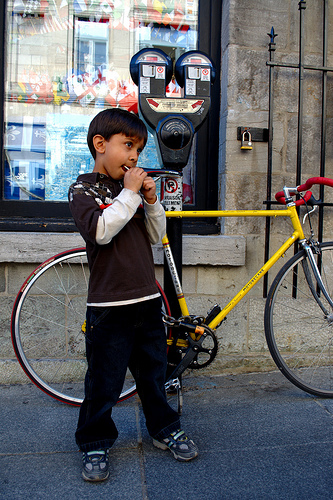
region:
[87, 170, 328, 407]
the bike is yellow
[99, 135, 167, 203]
little boy has sucker in mouth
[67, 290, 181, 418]
boy's pants are black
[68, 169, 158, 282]
boy's shirt is brown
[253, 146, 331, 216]
bike has red handles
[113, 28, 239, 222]
parking meter behind boy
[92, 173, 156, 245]
shirt has white sleeves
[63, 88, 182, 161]
boy's hair is brown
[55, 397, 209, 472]
shoes have velcro straps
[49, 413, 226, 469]
the shoes are gray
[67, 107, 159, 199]
young boy with popsicle in his mouth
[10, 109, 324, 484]
young boy standing in front of a bike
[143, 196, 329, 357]
a yellow frame on a bike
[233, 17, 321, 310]
a patalock on a gate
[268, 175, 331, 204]
red handle bars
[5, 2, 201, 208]
reflection of a building in the window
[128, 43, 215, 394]
a black parking meter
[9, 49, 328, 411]
a bike leaning against parking meter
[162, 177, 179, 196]
a small no parking sticker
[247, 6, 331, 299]
a black iron gate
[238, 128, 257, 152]
Silver and yellow padlock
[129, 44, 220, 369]
Dual side parking meter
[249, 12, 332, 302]
A black wrought iron fence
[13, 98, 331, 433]
A child in front of a bike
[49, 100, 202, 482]
Little boy enjoying a sucker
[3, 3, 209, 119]
Shop window displaying flags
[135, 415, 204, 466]
Gray and blue tennis shoe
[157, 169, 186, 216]
No parking sign on pole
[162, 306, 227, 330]
bike security chain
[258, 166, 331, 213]
red bike handle bars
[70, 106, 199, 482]
A young boy biting a white object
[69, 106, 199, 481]
A young boy wearing jeans and sneakers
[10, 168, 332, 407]
A red, black and yellow racing bike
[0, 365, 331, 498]
Black cemented passage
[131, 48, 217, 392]
A parking meter in a street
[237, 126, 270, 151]
Dark and yellow colored padlock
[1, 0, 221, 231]
A black frame window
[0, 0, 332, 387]
A building block next to the parking lot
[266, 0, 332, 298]
A metallic grille mounted to the building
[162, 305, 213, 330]
Chains fastening the racing bike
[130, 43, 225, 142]
a parking meter at the side of a road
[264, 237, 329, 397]
the wheel of a bicycle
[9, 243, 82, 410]
the wheel of a bicycle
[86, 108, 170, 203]
a little boy eating something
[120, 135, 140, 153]
the eye of a child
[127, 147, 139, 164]
the nose of a child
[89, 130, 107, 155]
the ear of a child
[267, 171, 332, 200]
red handle bars of a bicycle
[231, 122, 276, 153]
a padlock and clasp on a door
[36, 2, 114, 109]
a reflection of a window and flower in a window